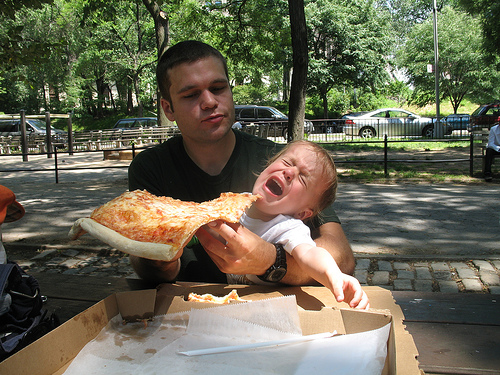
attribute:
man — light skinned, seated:
[128, 41, 357, 288]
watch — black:
[257, 243, 288, 285]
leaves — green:
[0, 0, 499, 115]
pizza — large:
[76, 187, 259, 262]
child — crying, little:
[201, 141, 367, 311]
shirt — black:
[128, 130, 343, 284]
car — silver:
[343, 107, 449, 139]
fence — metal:
[0, 116, 498, 157]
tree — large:
[288, 0, 311, 145]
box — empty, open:
[0, 282, 425, 374]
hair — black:
[156, 42, 231, 114]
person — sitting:
[210, 141, 366, 310]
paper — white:
[59, 295, 394, 374]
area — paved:
[0, 150, 498, 375]